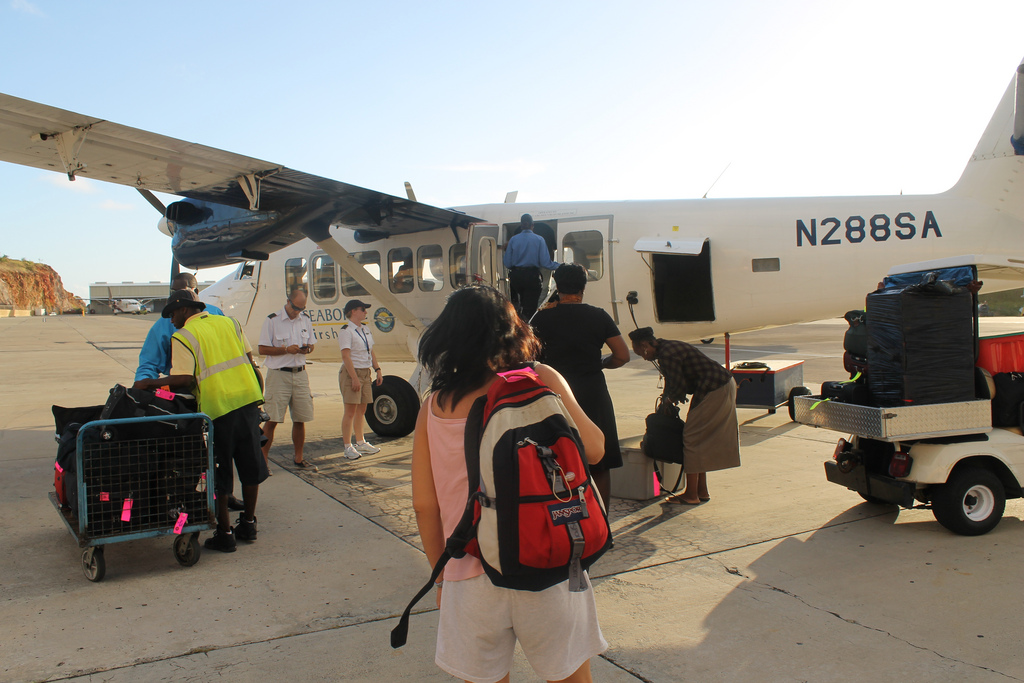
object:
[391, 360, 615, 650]
backpack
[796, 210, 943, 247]
n288sa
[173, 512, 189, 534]
pink tag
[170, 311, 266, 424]
yellow vest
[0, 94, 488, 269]
plane's wing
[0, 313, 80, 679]
concrete pavement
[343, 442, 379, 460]
white sneakers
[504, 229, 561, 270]
blue shirt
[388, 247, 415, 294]
plane windows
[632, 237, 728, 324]
cargo hatch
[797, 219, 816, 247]
letter n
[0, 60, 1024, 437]
plane